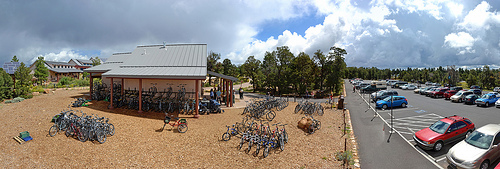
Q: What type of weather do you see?
A: It is cloudy.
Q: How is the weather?
A: It is cloudy.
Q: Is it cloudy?
A: Yes, it is cloudy.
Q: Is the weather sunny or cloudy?
A: It is cloudy.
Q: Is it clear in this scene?
A: No, it is cloudy.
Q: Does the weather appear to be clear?
A: No, it is cloudy.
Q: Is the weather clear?
A: No, it is cloudy.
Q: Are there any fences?
A: No, there are no fences.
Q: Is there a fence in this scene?
A: No, there are no fences.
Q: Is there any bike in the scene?
A: Yes, there is a bike.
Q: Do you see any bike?
A: Yes, there is a bike.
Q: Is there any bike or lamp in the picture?
A: Yes, there is a bike.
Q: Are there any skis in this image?
A: No, there are no skis.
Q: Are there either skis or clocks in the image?
A: No, there are no skis or clocks.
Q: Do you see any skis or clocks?
A: No, there are no skis or clocks.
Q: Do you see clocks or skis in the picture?
A: No, there are no skis or clocks.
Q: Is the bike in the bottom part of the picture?
A: Yes, the bike is in the bottom of the image.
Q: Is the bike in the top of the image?
A: No, the bike is in the bottom of the image.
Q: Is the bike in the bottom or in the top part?
A: The bike is in the bottom of the image.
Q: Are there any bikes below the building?
A: Yes, there is a bike below the building.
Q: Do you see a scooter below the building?
A: No, there is a bike below the building.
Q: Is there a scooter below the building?
A: No, there is a bike below the building.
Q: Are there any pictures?
A: No, there are no pictures.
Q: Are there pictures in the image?
A: No, there are no pictures.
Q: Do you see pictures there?
A: No, there are no pictures.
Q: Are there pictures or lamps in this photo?
A: No, there are no pictures or lamps.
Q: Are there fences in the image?
A: No, there are no fences.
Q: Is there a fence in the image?
A: No, there are no fences.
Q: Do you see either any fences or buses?
A: No, there are no fences or buses.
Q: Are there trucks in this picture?
A: No, there are no trucks.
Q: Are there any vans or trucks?
A: No, there are no trucks or vans.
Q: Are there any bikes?
A: Yes, there are bikes.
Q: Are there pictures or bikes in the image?
A: Yes, there are bikes.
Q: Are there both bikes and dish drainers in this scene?
A: No, there are bikes but no dish drainers.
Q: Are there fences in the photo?
A: No, there are no fences.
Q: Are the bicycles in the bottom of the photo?
A: Yes, the bicycles are in the bottom of the image.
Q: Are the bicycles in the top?
A: No, the bicycles are in the bottom of the image.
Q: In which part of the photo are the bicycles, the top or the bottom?
A: The bicycles are in the bottom of the image.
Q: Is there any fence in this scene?
A: No, there are no fences.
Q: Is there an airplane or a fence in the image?
A: No, there are no fences or airplanes.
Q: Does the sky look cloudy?
A: Yes, the sky is cloudy.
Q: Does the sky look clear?
A: No, the sky is cloudy.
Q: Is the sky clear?
A: No, the sky is cloudy.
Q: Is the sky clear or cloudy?
A: The sky is cloudy.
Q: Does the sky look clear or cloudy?
A: The sky is cloudy.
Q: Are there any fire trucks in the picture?
A: No, there are no fire trucks.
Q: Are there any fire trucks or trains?
A: No, there are no fire trucks or trains.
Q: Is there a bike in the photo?
A: Yes, there are bikes.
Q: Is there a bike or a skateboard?
A: Yes, there are bikes.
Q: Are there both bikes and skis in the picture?
A: No, there are bikes but no skis.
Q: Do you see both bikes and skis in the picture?
A: No, there are bikes but no skis.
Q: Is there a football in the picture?
A: No, there are no footballs.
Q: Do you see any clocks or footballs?
A: No, there are no footballs or clocks.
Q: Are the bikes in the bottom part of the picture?
A: Yes, the bikes are in the bottom of the image.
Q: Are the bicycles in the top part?
A: No, the bicycles are in the bottom of the image.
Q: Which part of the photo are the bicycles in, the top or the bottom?
A: The bicycles are in the bottom of the image.